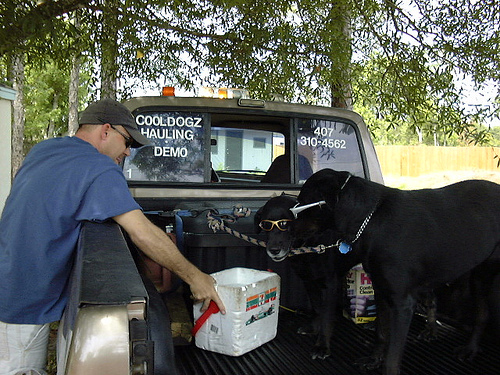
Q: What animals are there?
A: Dogs.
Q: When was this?
A: Daytime.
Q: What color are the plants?
A: Green.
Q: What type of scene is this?
A: Outdoor.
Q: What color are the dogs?
A: Black.